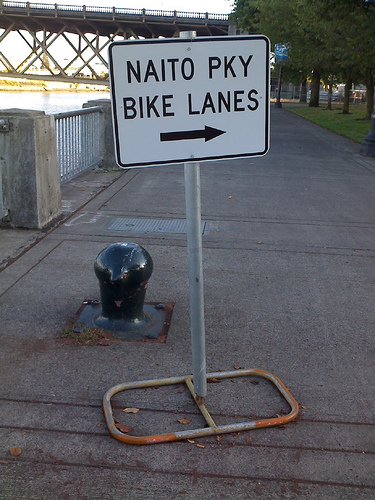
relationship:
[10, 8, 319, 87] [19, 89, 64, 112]
bridge over water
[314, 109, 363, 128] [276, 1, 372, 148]
grass at park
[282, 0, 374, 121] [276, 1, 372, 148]
trees at park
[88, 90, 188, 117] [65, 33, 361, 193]
bike on sign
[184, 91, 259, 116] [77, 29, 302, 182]
word on sign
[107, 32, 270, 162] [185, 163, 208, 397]
sign mounted on pole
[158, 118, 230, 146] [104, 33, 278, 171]
arrow on sign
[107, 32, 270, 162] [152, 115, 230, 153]
sign with arrow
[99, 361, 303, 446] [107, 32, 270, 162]
base of sign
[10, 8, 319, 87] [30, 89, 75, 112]
bridge over water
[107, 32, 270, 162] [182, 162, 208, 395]
sign on pole